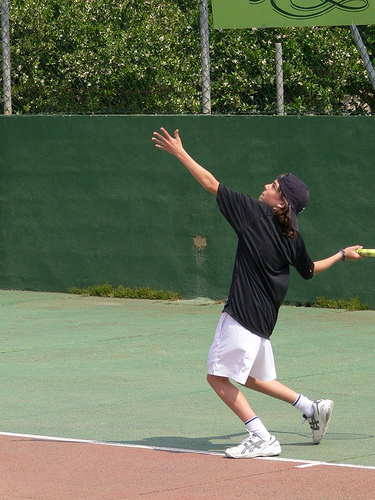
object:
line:
[0, 430, 375, 471]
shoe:
[303, 396, 333, 443]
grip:
[357, 247, 375, 258]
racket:
[356, 243, 374, 260]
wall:
[0, 113, 374, 312]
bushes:
[8, 0, 375, 113]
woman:
[148, 125, 366, 458]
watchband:
[341, 248, 348, 262]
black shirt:
[211, 180, 314, 340]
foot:
[222, 424, 282, 458]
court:
[0, 286, 375, 499]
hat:
[276, 171, 311, 232]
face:
[258, 180, 283, 206]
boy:
[151, 127, 363, 460]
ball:
[228, 325, 247, 353]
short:
[206, 312, 277, 384]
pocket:
[221, 321, 247, 358]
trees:
[0, 4, 375, 116]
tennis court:
[2, 287, 375, 500]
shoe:
[224, 428, 282, 458]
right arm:
[292, 232, 363, 281]